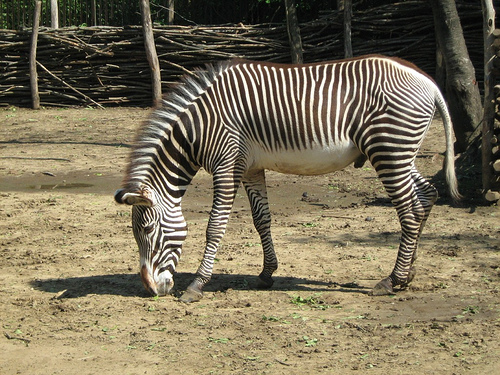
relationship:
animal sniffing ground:
[114, 53, 462, 299] [106, 296, 389, 355]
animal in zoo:
[114, 53, 462, 299] [6, 10, 488, 368]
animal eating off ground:
[114, 53, 462, 299] [2, 107, 498, 374]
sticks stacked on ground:
[5, 26, 193, 96] [9, 121, 113, 214]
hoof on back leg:
[368, 269, 415, 309] [365, 143, 424, 281]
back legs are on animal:
[366, 132, 446, 297] [114, 53, 462, 299]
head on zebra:
[110, 185, 194, 305] [115, 24, 482, 344]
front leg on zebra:
[194, 174, 238, 286] [92, 48, 470, 306]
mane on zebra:
[136, 99, 173, 144] [66, 24, 487, 329]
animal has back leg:
[114, 53, 462, 299] [364, 147, 426, 297]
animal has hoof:
[114, 53, 462, 299] [370, 274, 409, 295]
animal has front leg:
[114, 53, 462, 299] [194, 166, 244, 286]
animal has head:
[114, 53, 462, 299] [115, 190, 192, 300]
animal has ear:
[114, 53, 462, 299] [118, 183, 158, 205]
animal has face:
[114, 53, 462, 299] [129, 205, 162, 299]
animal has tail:
[114, 53, 462, 299] [439, 102, 460, 198]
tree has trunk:
[139, 2, 164, 104] [435, 4, 481, 204]